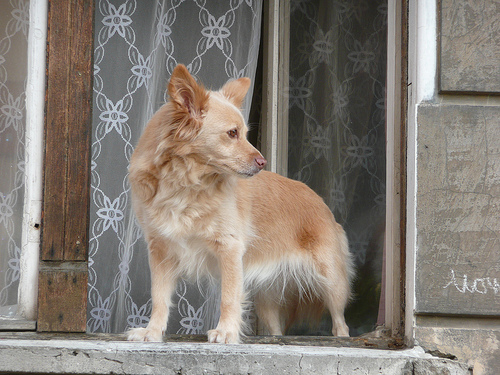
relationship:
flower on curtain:
[94, 195, 125, 235] [87, 3, 252, 322]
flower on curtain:
[94, 195, 125, 235] [91, 6, 289, 352]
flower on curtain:
[101, 195, 140, 248] [87, 3, 252, 322]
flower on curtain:
[94, 195, 125, 235] [94, 2, 277, 319]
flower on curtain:
[94, 195, 125, 235] [94, 2, 238, 349]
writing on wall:
[446, 270, 484, 294] [421, 4, 483, 337]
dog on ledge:
[122, 65, 358, 349] [0, 338, 475, 375]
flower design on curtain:
[103, 98, 130, 132] [94, 2, 277, 319]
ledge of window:
[0, 338, 475, 375] [6, 1, 304, 335]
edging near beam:
[19, 0, 39, 319] [40, 5, 91, 335]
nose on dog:
[253, 153, 267, 171] [122, 65, 358, 349]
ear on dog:
[165, 63, 207, 117] [131, 63, 371, 343]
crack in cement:
[295, 352, 305, 375] [11, 327, 480, 371]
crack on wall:
[295, 352, 305, 375] [404, 5, 481, 358]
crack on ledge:
[295, 352, 305, 375] [3, 334, 475, 373]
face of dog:
[214, 117, 264, 177] [122, 65, 358, 349]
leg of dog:
[208, 242, 244, 330] [122, 65, 358, 349]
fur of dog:
[136, 135, 312, 286] [117, 82, 364, 344]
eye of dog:
[227, 128, 237, 138] [122, 65, 358, 349]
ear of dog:
[165, 65, 198, 113] [122, 65, 358, 349]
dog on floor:
[122, 65, 358, 349] [2, 336, 435, 363]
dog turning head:
[122, 65, 358, 349] [167, 65, 263, 176]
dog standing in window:
[122, 65, 358, 349] [77, 10, 417, 355]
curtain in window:
[86, 0, 263, 334] [84, 13, 394, 343]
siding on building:
[414, 19, 481, 369] [5, 5, 481, 360]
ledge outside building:
[6, 328, 414, 372] [5, 5, 481, 360]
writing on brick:
[439, 267, 500, 296] [418, 100, 484, 310]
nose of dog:
[253, 153, 267, 173] [122, 65, 358, 349]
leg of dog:
[211, 241, 250, 350] [122, 65, 358, 349]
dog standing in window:
[122, 65, 358, 349] [5, 4, 411, 344]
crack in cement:
[295, 352, 305, 375] [0, 340, 475, 375]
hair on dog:
[144, 158, 329, 301] [122, 65, 358, 349]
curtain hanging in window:
[86, 0, 263, 334] [84, 13, 394, 343]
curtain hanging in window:
[289, 1, 389, 332] [84, 13, 394, 343]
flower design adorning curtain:
[197, 10, 232, 51] [87, 3, 252, 322]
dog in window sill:
[122, 65, 358, 349] [0, 327, 419, 362]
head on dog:
[143, 57, 267, 177] [122, 65, 358, 349]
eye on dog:
[227, 128, 237, 138] [122, 65, 358, 349]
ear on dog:
[165, 63, 207, 117] [122, 65, 358, 349]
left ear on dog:
[215, 73, 253, 106] [122, 65, 358, 349]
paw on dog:
[201, 316, 243, 343] [122, 65, 358, 349]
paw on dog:
[118, 321, 167, 343] [122, 65, 358, 349]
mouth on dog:
[216, 159, 258, 179] [122, 65, 358, 349]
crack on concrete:
[295, 352, 305, 375] [1, 333, 431, 373]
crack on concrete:
[295, 352, 305, 375] [2, 335, 440, 370]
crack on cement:
[66, 347, 96, 363] [0, 340, 475, 375]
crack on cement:
[102, 350, 126, 368] [0, 340, 475, 375]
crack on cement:
[295, 352, 305, 375] [0, 340, 475, 375]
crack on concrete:
[410, 361, 417, 375] [2, 335, 440, 370]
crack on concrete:
[66, 344, 98, 360] [2, 335, 440, 370]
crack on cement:
[100, 356, 123, 365] [0, 340, 475, 375]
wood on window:
[39, 3, 91, 331] [5, 4, 411, 344]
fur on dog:
[256, 204, 312, 249] [122, 65, 358, 349]